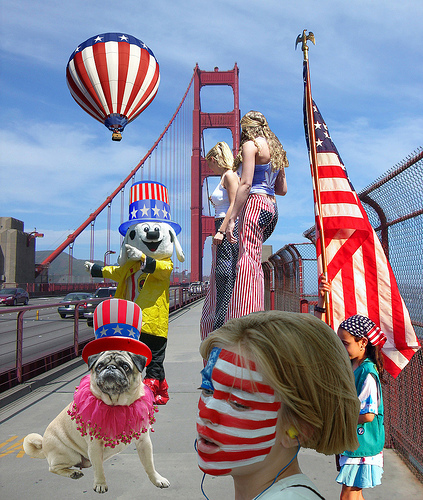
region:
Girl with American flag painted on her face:
[194, 312, 363, 498]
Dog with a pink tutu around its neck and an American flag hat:
[22, 295, 170, 492]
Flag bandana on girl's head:
[338, 314, 385, 366]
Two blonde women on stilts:
[201, 108, 287, 334]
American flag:
[293, 27, 419, 378]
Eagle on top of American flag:
[296, 26, 315, 50]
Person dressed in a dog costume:
[84, 178, 185, 402]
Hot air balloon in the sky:
[63, 32, 163, 142]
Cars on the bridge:
[0, 289, 114, 322]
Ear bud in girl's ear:
[283, 424, 315, 446]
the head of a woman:
[164, 319, 373, 483]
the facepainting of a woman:
[193, 359, 282, 469]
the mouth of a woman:
[195, 430, 233, 455]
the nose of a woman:
[188, 383, 237, 428]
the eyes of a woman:
[199, 370, 268, 422]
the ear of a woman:
[281, 410, 308, 451]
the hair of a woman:
[266, 346, 345, 404]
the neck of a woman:
[224, 459, 286, 497]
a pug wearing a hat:
[28, 288, 178, 460]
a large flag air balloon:
[61, 27, 178, 148]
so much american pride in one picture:
[33, 17, 411, 499]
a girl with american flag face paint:
[192, 306, 355, 472]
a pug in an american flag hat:
[27, 295, 185, 498]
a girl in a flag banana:
[333, 310, 393, 383]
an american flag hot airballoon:
[62, 23, 156, 143]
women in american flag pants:
[196, 112, 276, 310]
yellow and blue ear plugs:
[283, 424, 308, 455]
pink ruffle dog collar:
[54, 367, 163, 447]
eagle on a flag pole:
[289, 15, 324, 62]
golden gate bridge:
[185, 58, 270, 302]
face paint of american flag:
[195, 351, 275, 473]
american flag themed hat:
[80, 296, 150, 363]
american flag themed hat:
[119, 180, 179, 231]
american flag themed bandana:
[340, 314, 383, 347]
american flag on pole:
[311, 65, 420, 373]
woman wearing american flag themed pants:
[200, 195, 275, 337]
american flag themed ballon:
[64, 32, 162, 139]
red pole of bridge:
[30, 67, 196, 286]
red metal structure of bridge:
[190, 71, 238, 285]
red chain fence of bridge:
[258, 149, 420, 339]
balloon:
[68, 27, 153, 141]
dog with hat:
[59, 306, 154, 467]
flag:
[261, 39, 397, 298]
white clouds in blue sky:
[37, 121, 57, 160]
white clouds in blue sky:
[19, 184, 60, 203]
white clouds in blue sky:
[14, 145, 78, 207]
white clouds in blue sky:
[218, 20, 256, 56]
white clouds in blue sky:
[342, 37, 381, 75]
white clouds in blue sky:
[329, 55, 385, 104]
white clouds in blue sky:
[14, 35, 55, 74]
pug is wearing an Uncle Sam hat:
[24, 297, 170, 494]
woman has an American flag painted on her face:
[194, 309, 360, 498]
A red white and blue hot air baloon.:
[57, 27, 166, 144]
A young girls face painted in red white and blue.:
[182, 336, 285, 480]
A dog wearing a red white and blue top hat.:
[20, 290, 178, 493]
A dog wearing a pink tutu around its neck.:
[19, 295, 183, 496]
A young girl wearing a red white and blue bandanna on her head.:
[337, 312, 390, 360]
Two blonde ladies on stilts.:
[197, 107, 296, 377]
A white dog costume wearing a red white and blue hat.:
[79, 171, 184, 410]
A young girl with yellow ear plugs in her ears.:
[187, 312, 359, 481]